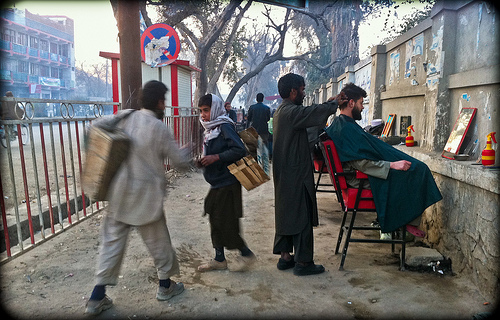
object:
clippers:
[338, 94, 347, 102]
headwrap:
[199, 93, 235, 141]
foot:
[84, 294, 114, 315]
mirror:
[441, 108, 478, 160]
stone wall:
[441, 17, 497, 101]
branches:
[135, 0, 358, 105]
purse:
[227, 154, 271, 191]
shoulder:
[220, 123, 234, 132]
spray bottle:
[405, 125, 415, 147]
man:
[80, 79, 195, 318]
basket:
[80, 123, 130, 202]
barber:
[272, 72, 348, 276]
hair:
[339, 82, 368, 111]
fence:
[0, 90, 201, 266]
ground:
[0, 169, 495, 318]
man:
[325, 82, 443, 238]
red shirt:
[0, 120, 100, 258]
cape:
[325, 114, 443, 233]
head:
[198, 93, 225, 122]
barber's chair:
[315, 139, 408, 271]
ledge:
[391, 145, 498, 193]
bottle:
[482, 131, 498, 167]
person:
[196, 93, 271, 272]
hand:
[335, 91, 348, 105]